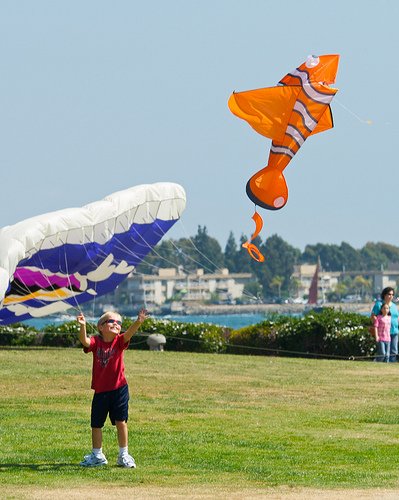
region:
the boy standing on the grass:
[72, 303, 151, 470]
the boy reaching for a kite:
[71, 303, 146, 470]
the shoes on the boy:
[73, 448, 136, 468]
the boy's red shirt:
[86, 332, 129, 387]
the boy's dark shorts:
[84, 383, 131, 427]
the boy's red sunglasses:
[98, 318, 121, 326]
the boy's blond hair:
[97, 311, 115, 320]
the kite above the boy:
[5, 181, 188, 328]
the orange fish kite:
[227, 51, 337, 263]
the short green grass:
[147, 361, 348, 467]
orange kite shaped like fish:
[224, 48, 352, 218]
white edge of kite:
[79, 180, 184, 228]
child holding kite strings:
[67, 295, 155, 473]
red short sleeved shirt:
[82, 331, 132, 400]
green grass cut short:
[161, 365, 269, 426]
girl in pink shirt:
[368, 298, 394, 349]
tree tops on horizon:
[302, 236, 381, 262]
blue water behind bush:
[197, 311, 261, 337]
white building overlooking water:
[145, 267, 245, 312]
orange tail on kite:
[234, 208, 268, 268]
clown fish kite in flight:
[220, 46, 345, 267]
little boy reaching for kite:
[71, 300, 151, 476]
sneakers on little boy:
[75, 445, 137, 472]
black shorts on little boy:
[85, 381, 136, 431]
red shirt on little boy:
[75, 329, 129, 396]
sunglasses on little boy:
[102, 314, 122, 325]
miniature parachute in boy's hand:
[0, 180, 186, 345]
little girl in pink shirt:
[372, 299, 390, 362]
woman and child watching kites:
[369, 284, 398, 366]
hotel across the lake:
[88, 256, 397, 306]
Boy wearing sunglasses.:
[85, 310, 141, 339]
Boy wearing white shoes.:
[64, 452, 179, 481]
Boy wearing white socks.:
[84, 447, 178, 450]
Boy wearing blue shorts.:
[93, 388, 171, 446]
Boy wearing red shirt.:
[87, 344, 165, 418]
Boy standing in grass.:
[48, 450, 180, 498]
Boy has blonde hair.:
[90, 313, 144, 340]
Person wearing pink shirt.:
[370, 312, 395, 358]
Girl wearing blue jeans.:
[368, 343, 391, 357]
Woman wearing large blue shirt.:
[375, 299, 390, 316]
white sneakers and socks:
[55, 448, 139, 494]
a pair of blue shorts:
[67, 386, 145, 450]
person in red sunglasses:
[94, 301, 128, 340]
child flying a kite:
[13, 224, 164, 351]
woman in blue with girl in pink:
[322, 292, 395, 407]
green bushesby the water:
[132, 304, 361, 361]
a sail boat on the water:
[252, 241, 343, 339]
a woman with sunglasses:
[374, 283, 394, 305]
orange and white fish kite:
[183, 40, 335, 236]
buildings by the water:
[123, 238, 345, 345]